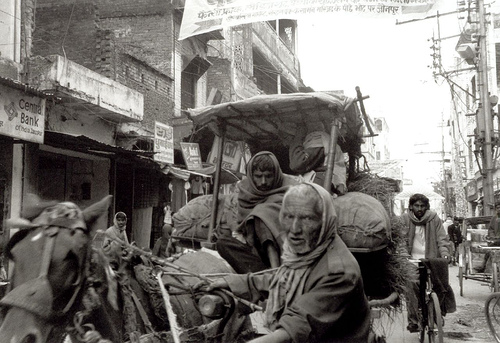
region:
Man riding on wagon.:
[181, 75, 361, 278]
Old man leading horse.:
[2, 181, 364, 340]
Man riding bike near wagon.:
[388, 171, 473, 340]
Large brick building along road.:
[12, 23, 182, 319]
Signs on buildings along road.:
[0, 74, 254, 198]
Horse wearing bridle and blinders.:
[1, 181, 132, 341]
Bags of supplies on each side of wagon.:
[175, 75, 418, 326]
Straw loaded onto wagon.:
[340, 119, 429, 322]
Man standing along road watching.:
[90, 170, 195, 289]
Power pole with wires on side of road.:
[415, 30, 498, 182]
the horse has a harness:
[5, 199, 107, 341]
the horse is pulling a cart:
[4, 99, 371, 336]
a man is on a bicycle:
[400, 198, 455, 341]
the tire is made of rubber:
[429, 292, 441, 342]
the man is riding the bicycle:
[398, 195, 457, 339]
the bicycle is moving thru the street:
[397, 195, 453, 337]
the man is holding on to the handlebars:
[395, 245, 451, 270]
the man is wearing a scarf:
[403, 208, 438, 226]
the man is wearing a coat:
[393, 208, 448, 265]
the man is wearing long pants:
[402, 260, 447, 321]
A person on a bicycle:
[390, 187, 472, 333]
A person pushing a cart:
[245, 192, 354, 338]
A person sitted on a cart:
[215, 140, 280, 246]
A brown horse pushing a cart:
[7, 190, 219, 336]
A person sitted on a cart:
[290, 111, 337, 174]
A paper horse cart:
[163, 85, 415, 205]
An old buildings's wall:
[8, 47, 154, 157]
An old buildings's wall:
[59, 2, 187, 52]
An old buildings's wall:
[236, 24, 312, 77]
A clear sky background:
[359, 45, 430, 130]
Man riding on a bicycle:
[394, 190, 456, 341]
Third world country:
[0, 0, 496, 342]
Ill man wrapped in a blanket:
[235, 150, 311, 277]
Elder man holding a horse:
[195, 178, 373, 340]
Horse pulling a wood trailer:
[0, 85, 415, 341]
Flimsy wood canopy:
[187, 84, 384, 146]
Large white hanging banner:
[172, 0, 451, 40]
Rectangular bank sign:
[0, 84, 47, 147]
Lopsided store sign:
[180, 139, 204, 173]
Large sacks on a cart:
[171, 185, 394, 257]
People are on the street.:
[0, 0, 497, 341]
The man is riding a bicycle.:
[390, 180, 455, 340]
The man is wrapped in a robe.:
[230, 150, 295, 255]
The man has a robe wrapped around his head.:
[240, 175, 360, 337]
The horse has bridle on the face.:
[0, 180, 115, 340]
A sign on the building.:
[0, 76, 45, 141]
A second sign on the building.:
[150, 115, 171, 161]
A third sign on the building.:
[180, 138, 206, 171]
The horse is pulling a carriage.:
[0, 90, 421, 340]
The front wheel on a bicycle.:
[421, 288, 442, 340]